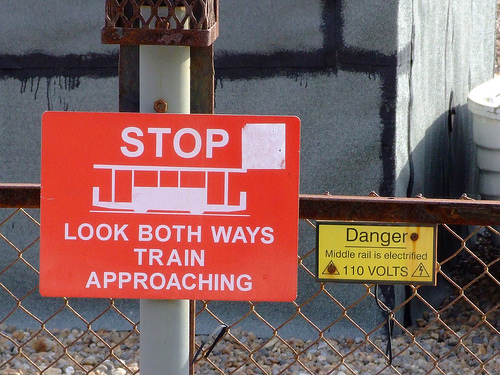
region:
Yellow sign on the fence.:
[311, 217, 438, 286]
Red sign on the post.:
[33, 103, 298, 304]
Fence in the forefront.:
[1, 179, 498, 374]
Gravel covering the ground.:
[5, 331, 497, 373]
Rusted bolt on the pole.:
[151, 99, 166, 113]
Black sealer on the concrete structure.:
[1, 0, 398, 322]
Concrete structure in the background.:
[0, 1, 497, 332]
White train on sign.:
[76, 158, 252, 216]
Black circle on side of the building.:
[442, 88, 458, 133]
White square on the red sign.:
[236, 123, 288, 169]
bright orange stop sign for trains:
[43, 112, 300, 303]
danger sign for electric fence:
[311, 222, 443, 289]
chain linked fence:
[1, 181, 487, 373]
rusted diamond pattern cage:
[88, 0, 223, 53]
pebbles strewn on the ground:
[0, 301, 499, 374]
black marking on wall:
[1, 1, 413, 333]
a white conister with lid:
[464, 73, 499, 239]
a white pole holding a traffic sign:
[125, 3, 202, 374]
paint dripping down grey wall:
[8, 69, 88, 134]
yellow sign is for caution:
[312, 225, 446, 292]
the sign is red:
[34, 105, 303, 308]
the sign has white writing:
[26, 101, 312, 314]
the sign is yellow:
[309, 209, 444, 290]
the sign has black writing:
[307, 212, 437, 294]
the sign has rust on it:
[307, 210, 447, 296]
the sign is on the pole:
[28, 100, 308, 311]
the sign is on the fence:
[304, 210, 448, 295]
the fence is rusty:
[0, 179, 498, 374]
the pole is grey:
[123, 2, 208, 374]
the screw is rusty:
[149, 90, 169, 123]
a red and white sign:
[32, 105, 307, 300]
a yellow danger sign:
[310, 216, 435, 283]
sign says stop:
[115, 116, 227, 161]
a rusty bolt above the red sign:
[150, 91, 167, 111]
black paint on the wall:
[0, 0, 415, 190]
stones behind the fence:
[0, 230, 495, 365]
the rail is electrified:
[0, 175, 491, 235]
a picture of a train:
[85, 155, 250, 215]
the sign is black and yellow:
[312, 215, 437, 286]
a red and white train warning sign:
[40, 110, 301, 301]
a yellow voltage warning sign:
[314, 219, 436, 283]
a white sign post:
[138, 6, 193, 373]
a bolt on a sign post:
[151, 99, 168, 112]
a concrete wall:
[2, 0, 412, 337]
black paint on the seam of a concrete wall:
[1, 45, 396, 87]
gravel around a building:
[0, 298, 499, 373]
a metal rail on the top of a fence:
[1, 182, 498, 223]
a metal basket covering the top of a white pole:
[101, 0, 219, 44]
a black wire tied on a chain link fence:
[372, 283, 402, 365]